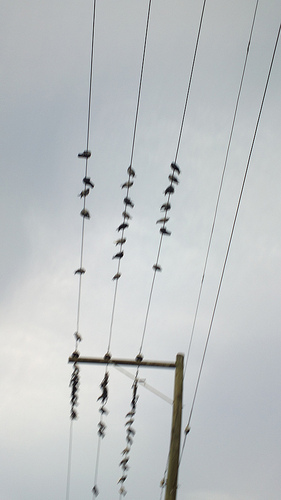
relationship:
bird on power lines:
[152, 162, 180, 272] [67, 6, 275, 399]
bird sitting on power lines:
[152, 162, 180, 272] [67, 6, 275, 399]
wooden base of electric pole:
[65, 355, 193, 500] [64, 335, 197, 499]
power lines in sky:
[67, 6, 275, 399] [4, 11, 279, 493]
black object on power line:
[72, 350, 82, 358] [64, 349, 196, 450]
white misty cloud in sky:
[10, 182, 63, 358] [0, 0, 279, 494]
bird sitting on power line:
[152, 162, 180, 272] [64, 349, 196, 450]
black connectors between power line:
[65, 351, 152, 362] [64, 349, 196, 450]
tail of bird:
[73, 151, 86, 160] [74, 149, 95, 159]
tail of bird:
[86, 180, 96, 188] [82, 177, 98, 187]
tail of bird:
[165, 230, 173, 236] [152, 162, 180, 272]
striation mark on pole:
[121, 364, 177, 394] [163, 356, 188, 498]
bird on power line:
[74, 149, 95, 276] [64, 349, 196, 450]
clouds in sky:
[23, 39, 238, 157] [4, 11, 279, 493]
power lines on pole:
[67, 6, 275, 399] [163, 356, 188, 498]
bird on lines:
[152, 162, 180, 272] [67, 6, 275, 399]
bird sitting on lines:
[152, 162, 180, 272] [67, 6, 275, 399]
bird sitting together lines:
[152, 162, 180, 272] [67, 6, 275, 399]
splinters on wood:
[170, 388, 188, 410] [163, 356, 188, 498]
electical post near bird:
[163, 356, 188, 498] [152, 162, 180, 272]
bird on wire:
[152, 162, 180, 272] [52, 15, 273, 340]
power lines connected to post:
[65, 0, 281, 500] [132, 358, 205, 500]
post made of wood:
[132, 358, 205, 500] [149, 358, 203, 498]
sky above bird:
[4, 11, 279, 493] [152, 162, 180, 272]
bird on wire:
[74, 149, 95, 276] [52, 15, 273, 340]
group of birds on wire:
[34, 126, 197, 299] [52, 15, 273, 340]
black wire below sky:
[67, 6, 275, 399] [4, 11, 279, 493]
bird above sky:
[74, 149, 95, 159] [4, 11, 279, 493]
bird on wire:
[112, 167, 136, 281] [52, 15, 273, 340]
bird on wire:
[117, 220, 130, 232] [52, 15, 273, 340]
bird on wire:
[69, 326, 89, 342] [52, 15, 273, 340]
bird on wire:
[165, 184, 179, 198] [52, 15, 273, 340]